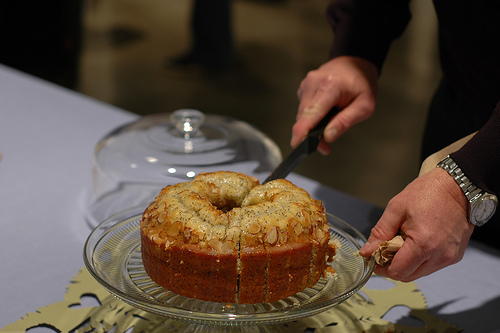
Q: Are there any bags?
A: No, there are no bags.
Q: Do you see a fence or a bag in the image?
A: No, there are no bags or fences.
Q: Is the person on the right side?
A: Yes, the person is on the right of the image.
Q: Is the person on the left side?
A: No, the person is on the right of the image.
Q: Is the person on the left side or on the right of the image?
A: The person is on the right of the image.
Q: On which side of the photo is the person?
A: The person is on the right of the image.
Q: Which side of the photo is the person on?
A: The person is on the right of the image.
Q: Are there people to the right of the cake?
A: Yes, there is a person to the right of the cake.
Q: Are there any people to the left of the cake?
A: No, the person is to the right of the cake.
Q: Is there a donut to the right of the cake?
A: No, there is a person to the right of the cake.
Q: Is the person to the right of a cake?
A: Yes, the person is to the right of a cake.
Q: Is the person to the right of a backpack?
A: No, the person is to the right of a cake.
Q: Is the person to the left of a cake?
A: No, the person is to the right of a cake.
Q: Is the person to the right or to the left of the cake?
A: The person is to the right of the cake.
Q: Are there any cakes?
A: Yes, there is a cake.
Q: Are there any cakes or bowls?
A: Yes, there is a cake.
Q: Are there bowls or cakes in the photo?
A: Yes, there is a cake.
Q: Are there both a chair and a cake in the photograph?
A: No, there is a cake but no chairs.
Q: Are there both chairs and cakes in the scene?
A: No, there is a cake but no chairs.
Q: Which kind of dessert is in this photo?
A: The dessert is a cake.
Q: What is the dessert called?
A: The dessert is a cake.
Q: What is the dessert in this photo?
A: The dessert is a cake.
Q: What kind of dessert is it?
A: The dessert is a cake.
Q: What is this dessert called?
A: This is a cake.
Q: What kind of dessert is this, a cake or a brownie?
A: This is a cake.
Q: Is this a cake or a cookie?
A: This is a cake.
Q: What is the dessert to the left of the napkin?
A: The dessert is a cake.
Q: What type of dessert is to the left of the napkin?
A: The dessert is a cake.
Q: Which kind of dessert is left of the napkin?
A: The dessert is a cake.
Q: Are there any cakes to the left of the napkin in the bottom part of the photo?
A: Yes, there is a cake to the left of the napkin.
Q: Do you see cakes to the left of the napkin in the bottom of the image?
A: Yes, there is a cake to the left of the napkin.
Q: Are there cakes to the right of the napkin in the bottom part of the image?
A: No, the cake is to the left of the napkin.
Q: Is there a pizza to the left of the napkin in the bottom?
A: No, there is a cake to the left of the napkin.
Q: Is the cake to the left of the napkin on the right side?
A: Yes, the cake is to the left of the napkin.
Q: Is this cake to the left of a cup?
A: No, the cake is to the left of the napkin.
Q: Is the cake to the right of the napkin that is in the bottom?
A: No, the cake is to the left of the napkin.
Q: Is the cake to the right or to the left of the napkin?
A: The cake is to the left of the napkin.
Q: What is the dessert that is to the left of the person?
A: The dessert is a cake.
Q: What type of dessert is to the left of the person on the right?
A: The dessert is a cake.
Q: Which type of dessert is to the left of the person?
A: The dessert is a cake.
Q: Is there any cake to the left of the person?
A: Yes, there is a cake to the left of the person.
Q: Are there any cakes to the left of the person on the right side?
A: Yes, there is a cake to the left of the person.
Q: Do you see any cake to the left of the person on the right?
A: Yes, there is a cake to the left of the person.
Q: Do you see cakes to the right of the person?
A: No, the cake is to the left of the person.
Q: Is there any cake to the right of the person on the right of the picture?
A: No, the cake is to the left of the person.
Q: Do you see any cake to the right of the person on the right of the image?
A: No, the cake is to the left of the person.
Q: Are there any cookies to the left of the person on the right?
A: No, there is a cake to the left of the person.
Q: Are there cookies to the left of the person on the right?
A: No, there is a cake to the left of the person.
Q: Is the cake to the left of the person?
A: Yes, the cake is to the left of the person.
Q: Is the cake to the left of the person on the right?
A: Yes, the cake is to the left of the person.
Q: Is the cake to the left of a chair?
A: No, the cake is to the left of the person.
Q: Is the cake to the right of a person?
A: No, the cake is to the left of a person.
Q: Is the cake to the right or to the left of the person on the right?
A: The cake is to the left of the person.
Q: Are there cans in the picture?
A: No, there are no cans.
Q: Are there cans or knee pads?
A: No, there are no cans or knee pads.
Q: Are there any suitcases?
A: No, there are no suitcases.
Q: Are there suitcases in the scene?
A: No, there are no suitcases.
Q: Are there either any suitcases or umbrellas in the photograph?
A: No, there are no suitcases or umbrellas.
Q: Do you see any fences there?
A: No, there are no fences.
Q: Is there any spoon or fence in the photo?
A: No, there are no fences or spoons.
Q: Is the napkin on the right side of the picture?
A: Yes, the napkin is on the right of the image.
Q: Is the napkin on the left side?
A: No, the napkin is on the right of the image.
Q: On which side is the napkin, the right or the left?
A: The napkin is on the right of the image.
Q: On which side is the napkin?
A: The napkin is on the right of the image.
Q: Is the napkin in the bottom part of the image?
A: Yes, the napkin is in the bottom of the image.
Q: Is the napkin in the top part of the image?
A: No, the napkin is in the bottom of the image.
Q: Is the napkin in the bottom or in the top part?
A: The napkin is in the bottom of the image.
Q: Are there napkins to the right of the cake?
A: Yes, there is a napkin to the right of the cake.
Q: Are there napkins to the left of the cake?
A: No, the napkin is to the right of the cake.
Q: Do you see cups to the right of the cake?
A: No, there is a napkin to the right of the cake.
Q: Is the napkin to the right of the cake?
A: Yes, the napkin is to the right of the cake.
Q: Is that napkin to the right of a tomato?
A: No, the napkin is to the right of the cake.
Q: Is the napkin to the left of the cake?
A: No, the napkin is to the right of the cake.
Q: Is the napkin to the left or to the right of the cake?
A: The napkin is to the right of the cake.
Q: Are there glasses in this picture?
A: No, there are no glasses.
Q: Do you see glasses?
A: No, there are no glasses.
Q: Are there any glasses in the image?
A: No, there are no glasses.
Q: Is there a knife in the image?
A: Yes, there is a knife.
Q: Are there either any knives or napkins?
A: Yes, there is a knife.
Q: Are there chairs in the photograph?
A: No, there are no chairs.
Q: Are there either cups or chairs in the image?
A: No, there are no chairs or cups.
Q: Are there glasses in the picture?
A: No, there are no glasses.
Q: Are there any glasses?
A: No, there are no glasses.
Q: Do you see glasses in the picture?
A: No, there are no glasses.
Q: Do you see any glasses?
A: No, there are no glasses.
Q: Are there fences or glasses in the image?
A: No, there are no glasses or fences.